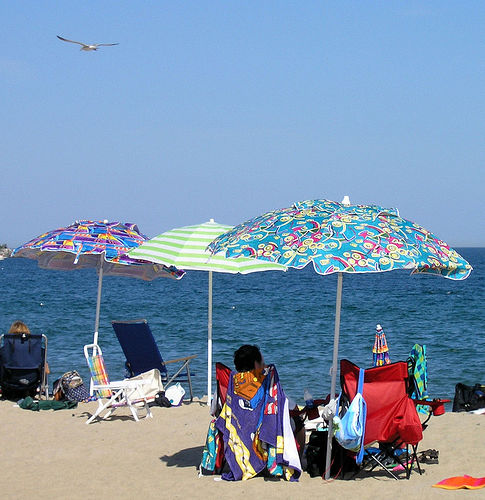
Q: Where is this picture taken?
A: It is taken on the beach.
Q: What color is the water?
A: The water is blue.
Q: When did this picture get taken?
A: It was taken in the day time.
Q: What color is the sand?
A: The sand is brown.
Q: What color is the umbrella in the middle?
A: The umbrella is green and white.